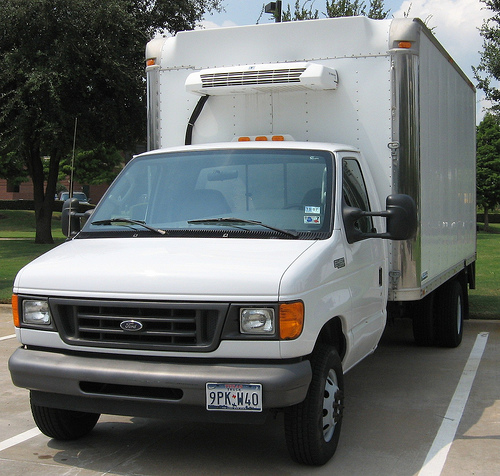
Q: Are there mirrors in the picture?
A: Yes, there is a mirror.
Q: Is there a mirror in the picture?
A: Yes, there is a mirror.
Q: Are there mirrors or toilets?
A: Yes, there is a mirror.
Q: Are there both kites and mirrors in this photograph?
A: No, there is a mirror but no kites.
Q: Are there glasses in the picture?
A: No, there are no glasses.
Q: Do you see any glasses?
A: No, there are no glasses.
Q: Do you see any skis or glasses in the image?
A: No, there are no glasses or skis.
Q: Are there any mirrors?
A: Yes, there is a mirror.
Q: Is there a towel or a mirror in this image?
A: Yes, there is a mirror.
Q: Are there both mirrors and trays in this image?
A: No, there is a mirror but no trays.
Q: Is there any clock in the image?
A: No, there are no clocks.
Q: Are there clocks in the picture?
A: No, there are no clocks.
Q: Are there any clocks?
A: No, there are no clocks.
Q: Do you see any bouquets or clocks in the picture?
A: No, there are no clocks or bouquets.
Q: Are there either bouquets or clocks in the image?
A: No, there are no clocks or bouquets.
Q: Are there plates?
A: Yes, there is a plate.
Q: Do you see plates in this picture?
A: Yes, there is a plate.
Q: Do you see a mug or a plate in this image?
A: Yes, there is a plate.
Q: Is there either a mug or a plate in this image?
A: Yes, there is a plate.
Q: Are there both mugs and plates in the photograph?
A: No, there is a plate but no mugs.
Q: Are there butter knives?
A: No, there are no butter knives.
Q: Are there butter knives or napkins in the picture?
A: No, there are no butter knives or napkins.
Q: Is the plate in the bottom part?
A: Yes, the plate is in the bottom of the image.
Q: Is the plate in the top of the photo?
A: No, the plate is in the bottom of the image.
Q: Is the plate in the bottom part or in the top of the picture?
A: The plate is in the bottom of the image.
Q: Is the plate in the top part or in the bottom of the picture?
A: The plate is in the bottom of the image.